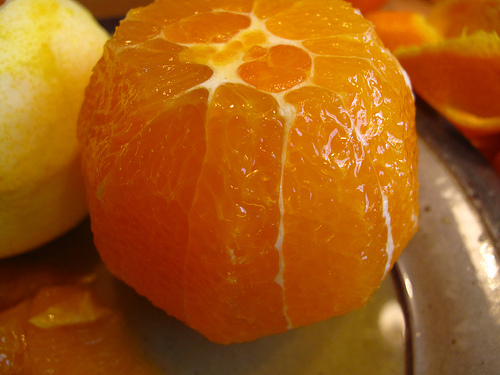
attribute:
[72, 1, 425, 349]
peeled orange — wet, oval shaped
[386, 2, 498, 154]
peels — orange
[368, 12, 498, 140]
rind — porous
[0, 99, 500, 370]
plate — silver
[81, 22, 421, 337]
orange — skinless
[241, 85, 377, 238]
orange — peeled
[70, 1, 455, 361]
orange — peeled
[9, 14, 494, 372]
plate — well-used, metal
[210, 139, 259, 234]
orange — shiny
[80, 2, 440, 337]
orange — Peeled , orange , white., smaller, inner, slice, wet, skinless, without it's rind